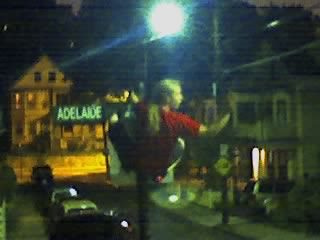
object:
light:
[251, 145, 269, 180]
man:
[106, 79, 231, 184]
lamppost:
[136, 36, 154, 240]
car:
[44, 211, 137, 240]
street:
[28, 173, 240, 239]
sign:
[213, 157, 233, 177]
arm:
[175, 114, 227, 138]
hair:
[143, 78, 184, 138]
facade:
[10, 54, 74, 149]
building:
[8, 53, 76, 156]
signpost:
[221, 172, 229, 222]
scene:
[0, 1, 318, 239]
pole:
[99, 95, 111, 182]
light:
[140, 0, 198, 38]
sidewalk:
[148, 190, 320, 240]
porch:
[240, 146, 289, 186]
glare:
[57, 25, 144, 69]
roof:
[8, 51, 78, 90]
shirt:
[119, 104, 202, 170]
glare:
[253, 180, 258, 195]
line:
[224, 41, 320, 76]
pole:
[210, 0, 225, 123]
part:
[9, 69, 27, 87]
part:
[197, 123, 208, 137]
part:
[145, 185, 245, 238]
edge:
[153, 201, 241, 239]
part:
[109, 166, 121, 175]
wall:
[304, 136, 313, 172]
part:
[168, 0, 193, 15]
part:
[28, 101, 34, 107]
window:
[27, 93, 35, 110]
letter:
[56, 105, 102, 121]